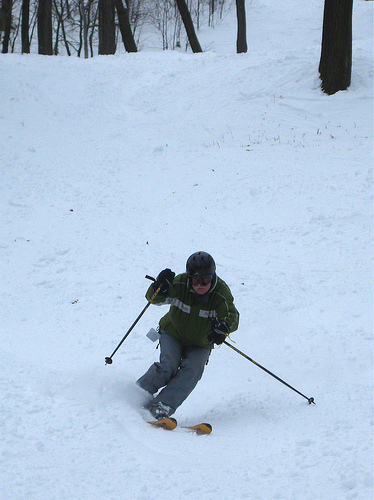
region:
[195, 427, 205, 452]
part of a board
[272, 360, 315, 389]
part of a hooker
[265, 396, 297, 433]
part of a snoew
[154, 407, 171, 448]
part of a board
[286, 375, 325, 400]
part of a hooker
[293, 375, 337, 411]
part of a hooker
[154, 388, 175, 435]
part of a shaoe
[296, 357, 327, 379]
part of a ground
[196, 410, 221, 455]
part of a board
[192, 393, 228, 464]
part of a board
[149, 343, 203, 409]
the pants are grey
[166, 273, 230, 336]
the jacket is green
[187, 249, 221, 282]
the helmet is black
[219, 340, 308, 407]
the skipole is black and yellow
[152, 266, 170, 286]
the gloves are black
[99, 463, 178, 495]
the snow is white in color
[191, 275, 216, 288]
the goggles are on his face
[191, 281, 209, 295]
the beard is white in color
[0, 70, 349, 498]
the ground is sloppy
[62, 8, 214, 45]
trees are in the background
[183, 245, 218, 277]
the black helmet on the mans head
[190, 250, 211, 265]
the slits in the black helmet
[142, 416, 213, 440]
the orange skies in the snow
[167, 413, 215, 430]
the black tip of the skies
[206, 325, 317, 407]
the ski pole in the mans hand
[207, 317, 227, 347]
the glove on the mans hand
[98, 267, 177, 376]
the man holding the ski pole in the air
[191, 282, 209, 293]
the mustache on the mans lip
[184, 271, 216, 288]
the googles on the mans face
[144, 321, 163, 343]
the tag on the mans jacket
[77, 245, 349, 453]
skier going down hill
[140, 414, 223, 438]
yellow skis on top of the snow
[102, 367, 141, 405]
snow flying up from the skis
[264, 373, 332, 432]
ski pole touching the ground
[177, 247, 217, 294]
black helmet on the skier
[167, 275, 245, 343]
green jacket with a grey stripe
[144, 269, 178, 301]
black gloves on the skier's hands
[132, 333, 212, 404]
skier is wearing grey pants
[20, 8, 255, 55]
trees above the slope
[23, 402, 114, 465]
white snow covers the ground